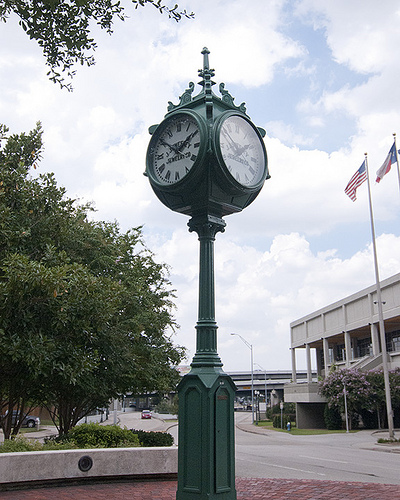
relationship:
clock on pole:
[146, 108, 269, 194] [177, 234, 219, 447]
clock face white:
[146, 108, 269, 194] [168, 169, 180, 187]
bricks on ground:
[8, 465, 397, 500] [19, 426, 398, 500]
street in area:
[0, 392, 399, 499] [67, 246, 370, 498]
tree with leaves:
[318, 365, 396, 431] [322, 366, 375, 412]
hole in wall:
[78, 454, 94, 478] [0, 451, 177, 487]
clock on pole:
[144, 110, 267, 219] [178, 214, 240, 499]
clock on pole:
[146, 108, 269, 194] [181, 215, 233, 498]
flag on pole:
[344, 160, 368, 202] [361, 147, 393, 443]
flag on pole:
[375, 144, 398, 184] [384, 129, 398, 185]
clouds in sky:
[0, 3, 395, 375] [0, 7, 398, 366]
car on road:
[141, 410, 152, 419] [107, 403, 399, 484]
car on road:
[6, 409, 40, 432] [18, 394, 399, 485]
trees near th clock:
[2, 123, 182, 432] [146, 108, 269, 194]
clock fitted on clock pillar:
[146, 108, 269, 194] [173, 214, 238, 500]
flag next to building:
[380, 144, 398, 184] [283, 266, 396, 430]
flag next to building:
[338, 163, 368, 200] [283, 266, 396, 430]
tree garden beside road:
[2, 121, 188, 443] [53, 395, 399, 476]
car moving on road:
[139, 410, 157, 423] [128, 417, 398, 483]